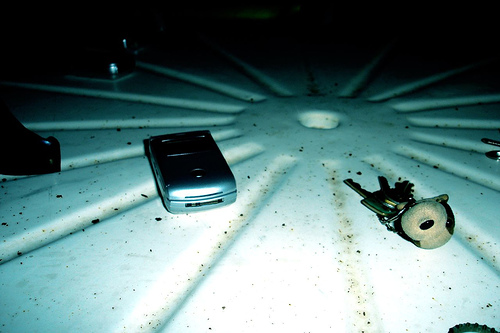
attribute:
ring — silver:
[380, 198, 416, 225]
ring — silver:
[381, 212, 408, 233]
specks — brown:
[320, 144, 377, 180]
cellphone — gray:
[148, 130, 236, 210]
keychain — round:
[398, 199, 454, 246]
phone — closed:
[142, 125, 238, 214]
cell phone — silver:
[144, 129, 236, 211]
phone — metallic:
[145, 130, 235, 210]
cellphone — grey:
[144, 137, 245, 209]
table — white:
[3, 4, 497, 329]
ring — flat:
[399, 181, 453, 259]